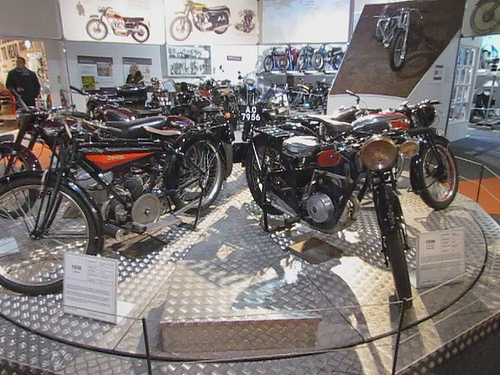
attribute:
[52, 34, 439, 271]
bikes — red, black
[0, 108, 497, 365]
display — circular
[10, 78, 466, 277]
bikes — old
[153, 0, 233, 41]
yellow/black bike — yellow, black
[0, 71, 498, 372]
display — metal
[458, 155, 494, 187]
stripe — yellow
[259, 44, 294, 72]
bike — small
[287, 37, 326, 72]
bike — small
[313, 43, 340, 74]
bike — small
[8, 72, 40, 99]
coat — black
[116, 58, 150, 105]
woman — old